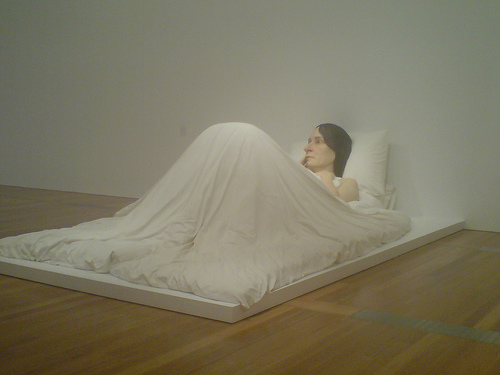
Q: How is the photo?
A: Blurry.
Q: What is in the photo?
A: A woman.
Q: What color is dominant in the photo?
A: White.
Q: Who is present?
A: A lady.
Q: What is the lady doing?
A: Relaxing.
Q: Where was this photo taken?
A: In a bedroom.